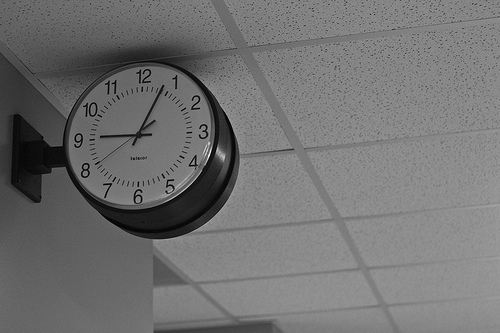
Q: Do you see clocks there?
A: Yes, there is a clock.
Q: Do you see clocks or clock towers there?
A: Yes, there is a clock.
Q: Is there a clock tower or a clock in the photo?
A: Yes, there is a clock.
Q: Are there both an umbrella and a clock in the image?
A: No, there is a clock but no umbrellas.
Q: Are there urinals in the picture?
A: No, there are no urinals.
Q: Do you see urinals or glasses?
A: No, there are no urinals or glasses.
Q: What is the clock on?
A: The clock is on the wall.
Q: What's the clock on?
A: The clock is on the wall.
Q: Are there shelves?
A: No, there are no shelves.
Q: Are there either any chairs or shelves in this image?
A: No, there are no shelves or chairs.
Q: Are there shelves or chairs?
A: No, there are no shelves or chairs.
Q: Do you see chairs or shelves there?
A: No, there are no shelves or chairs.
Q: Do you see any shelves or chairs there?
A: No, there are no shelves or chairs.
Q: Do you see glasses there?
A: No, there are no glasses.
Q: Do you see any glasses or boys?
A: No, there are no glasses or boys.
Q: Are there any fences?
A: No, there are no fences.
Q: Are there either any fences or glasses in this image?
A: No, there are no fences or glasses.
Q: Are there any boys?
A: No, there are no boys.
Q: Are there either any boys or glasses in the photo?
A: No, there are no boys or glasses.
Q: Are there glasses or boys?
A: No, there are no boys or glasses.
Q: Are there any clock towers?
A: No, there are no clock towers.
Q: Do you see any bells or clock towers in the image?
A: No, there are no clock towers or bells.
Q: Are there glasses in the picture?
A: No, there are no glasses.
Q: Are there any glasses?
A: No, there are no glasses.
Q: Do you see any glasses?
A: No, there are no glasses.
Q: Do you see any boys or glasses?
A: No, there are no glasses or boys.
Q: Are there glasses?
A: No, there are no glasses.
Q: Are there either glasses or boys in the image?
A: No, there are no glasses or boys.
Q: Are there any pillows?
A: No, there are no pillows.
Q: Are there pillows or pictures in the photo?
A: No, there are no pillows or pictures.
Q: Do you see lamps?
A: No, there are no lamps.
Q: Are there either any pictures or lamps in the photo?
A: No, there are no lamps or pictures.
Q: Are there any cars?
A: No, there are no cars.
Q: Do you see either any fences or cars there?
A: No, there are no cars or fences.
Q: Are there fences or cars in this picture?
A: No, there are no cars or fences.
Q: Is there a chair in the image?
A: No, there are no chairs.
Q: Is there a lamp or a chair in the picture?
A: No, there are no chairs or lamps.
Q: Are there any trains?
A: No, there are no trains.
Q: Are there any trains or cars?
A: No, there are no trains or cars.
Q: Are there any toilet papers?
A: No, there are no toilet papers.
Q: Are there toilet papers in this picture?
A: No, there are no toilet papers.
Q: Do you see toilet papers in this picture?
A: No, there are no toilet papers.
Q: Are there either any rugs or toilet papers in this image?
A: No, there are no toilet papers or rugs.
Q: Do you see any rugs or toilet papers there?
A: No, there are no toilet papers or rugs.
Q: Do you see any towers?
A: No, there are no towers.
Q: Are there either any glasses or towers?
A: No, there are no towers or glasses.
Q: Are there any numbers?
A: Yes, there are numbers.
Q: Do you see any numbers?
A: Yes, there are numbers.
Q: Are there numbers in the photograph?
A: Yes, there are numbers.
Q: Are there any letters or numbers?
A: Yes, there are numbers.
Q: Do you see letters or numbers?
A: Yes, there are numbers.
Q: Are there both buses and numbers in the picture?
A: No, there are numbers but no buses.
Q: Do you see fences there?
A: No, there are no fences.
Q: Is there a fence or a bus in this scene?
A: No, there are no fences or buses.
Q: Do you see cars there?
A: No, there are no cars.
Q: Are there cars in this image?
A: No, there are no cars.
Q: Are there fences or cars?
A: No, there are no cars or fences.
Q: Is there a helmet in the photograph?
A: No, there are no helmets.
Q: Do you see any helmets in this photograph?
A: No, there are no helmets.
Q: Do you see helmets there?
A: No, there are no helmets.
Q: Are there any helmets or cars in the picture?
A: No, there are no helmets or cars.